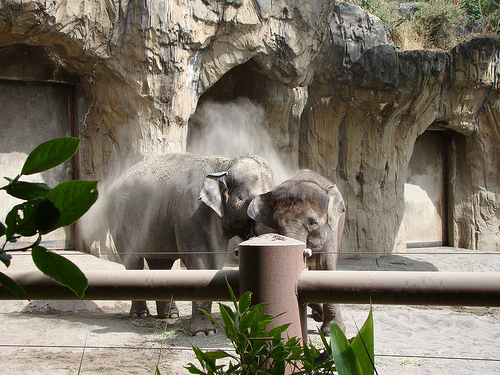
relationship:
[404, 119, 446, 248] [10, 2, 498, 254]
door on wall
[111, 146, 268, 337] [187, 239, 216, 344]
elephant has foot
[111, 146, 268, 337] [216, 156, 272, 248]
elephant has head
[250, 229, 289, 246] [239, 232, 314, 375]
dirt on post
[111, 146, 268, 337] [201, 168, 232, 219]
elephant has ear